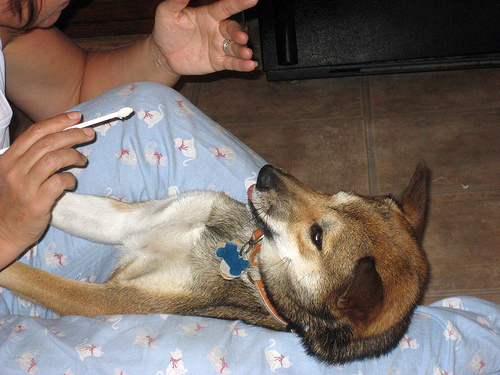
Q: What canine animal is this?
A: Dog.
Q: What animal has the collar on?
A: Dog.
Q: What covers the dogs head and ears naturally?
A: Fur.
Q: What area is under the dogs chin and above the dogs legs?
A: Chest area.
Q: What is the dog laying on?
A: A persons legs.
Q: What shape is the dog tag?
A: A bone.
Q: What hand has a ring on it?
A: Left hand.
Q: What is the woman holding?
A: A Q-tip.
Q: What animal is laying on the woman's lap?
A: A dog.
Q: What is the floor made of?
A: Tile.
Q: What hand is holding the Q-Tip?
A: Right hand.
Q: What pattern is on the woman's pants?
A: Cats.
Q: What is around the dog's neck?
A: A collar.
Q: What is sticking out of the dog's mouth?
A: Tongue.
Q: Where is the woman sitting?
A: On the ground.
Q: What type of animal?
A: Dog.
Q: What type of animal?
A: Dog.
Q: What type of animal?
A: Dog.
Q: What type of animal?
A: Dog.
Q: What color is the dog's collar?
A: Orange.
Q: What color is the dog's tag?
A: Blue.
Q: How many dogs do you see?
A: 1.